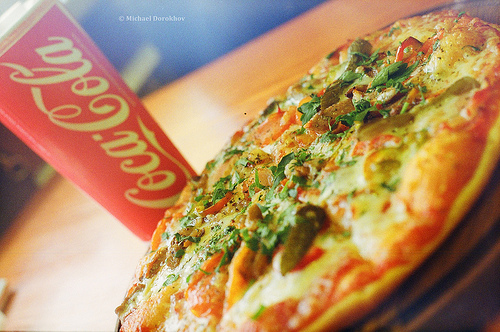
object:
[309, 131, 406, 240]
pizza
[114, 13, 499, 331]
pizza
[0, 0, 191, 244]
cup